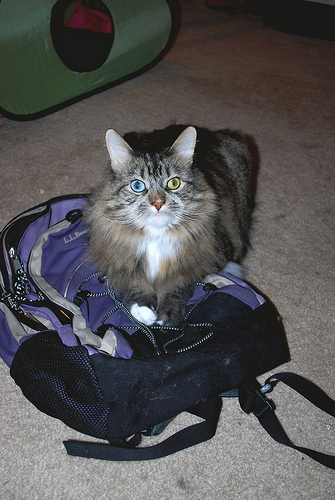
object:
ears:
[169, 123, 198, 174]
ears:
[104, 128, 134, 176]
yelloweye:
[171, 179, 174, 182]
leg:
[114, 264, 159, 328]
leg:
[157, 291, 186, 329]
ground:
[0, 118, 53, 193]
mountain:
[261, 109, 275, 298]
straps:
[238, 368, 335, 472]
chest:
[131, 230, 181, 289]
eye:
[166, 177, 181, 191]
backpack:
[0, 192, 334, 470]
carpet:
[0, 46, 335, 500]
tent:
[0, 0, 181, 123]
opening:
[50, 0, 116, 74]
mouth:
[154, 212, 162, 217]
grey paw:
[155, 299, 185, 327]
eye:
[130, 178, 147, 194]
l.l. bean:
[63, 234, 74, 244]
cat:
[81, 122, 253, 328]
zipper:
[8, 246, 16, 259]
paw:
[130, 303, 157, 326]